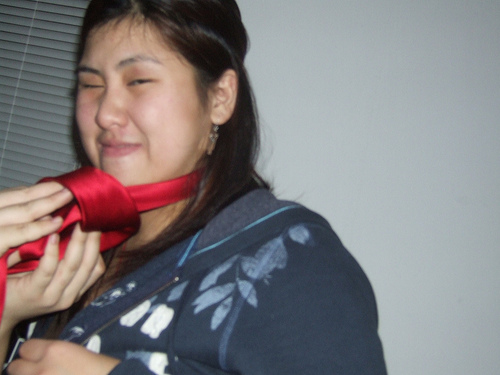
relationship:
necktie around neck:
[0, 165, 202, 326] [98, 162, 211, 245]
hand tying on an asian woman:
[0, 182, 73, 259] [0, 1, 390, 373]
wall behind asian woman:
[266, 0, 496, 246] [0, 1, 387, 374]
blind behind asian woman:
[0, 1, 87, 192] [0, 1, 387, 374]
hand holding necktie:
[0, 182, 73, 259] [0, 165, 202, 326]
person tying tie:
[0, 169, 107, 317] [30, 162, 146, 253]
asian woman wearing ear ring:
[0, 1, 387, 374] [202, 123, 222, 155]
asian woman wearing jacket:
[0, 1, 387, 374] [145, 196, 362, 338]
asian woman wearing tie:
[0, 1, 387, 374] [48, 164, 146, 250]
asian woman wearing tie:
[0, 1, 387, 374] [55, 161, 250, 276]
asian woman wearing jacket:
[0, 1, 387, 374] [1, 43, 415, 372]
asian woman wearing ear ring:
[0, 1, 387, 374] [206, 118, 224, 154]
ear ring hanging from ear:
[206, 118, 224, 154] [208, 68, 236, 124]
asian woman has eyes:
[0, 1, 387, 374] [124, 76, 158, 88]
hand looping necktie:
[0, 182, 72, 244] [40, 167, 202, 262]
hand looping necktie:
[6, 223, 113, 323] [40, 167, 202, 262]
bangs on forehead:
[83, 9, 163, 35] [70, 10, 175, 70]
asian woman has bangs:
[0, 1, 387, 374] [83, 9, 163, 35]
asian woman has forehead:
[0, 1, 387, 374] [70, 10, 175, 70]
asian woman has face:
[0, 1, 387, 374] [55, 22, 231, 189]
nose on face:
[88, 86, 129, 131] [55, 22, 231, 189]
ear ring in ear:
[206, 118, 224, 154] [208, 68, 239, 125]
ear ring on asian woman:
[206, 118, 224, 154] [0, 1, 387, 374]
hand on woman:
[10, 329, 130, 372] [20, 6, 363, 369]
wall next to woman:
[380, 5, 497, 373] [239, 0, 497, 368]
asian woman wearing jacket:
[0, 1, 387, 374] [116, 193, 393, 373]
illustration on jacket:
[79, 211, 304, 372] [13, 197, 390, 364]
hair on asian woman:
[68, 0, 271, 313] [0, 1, 387, 374]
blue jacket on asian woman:
[0, 187, 388, 373] [0, 1, 387, 374]